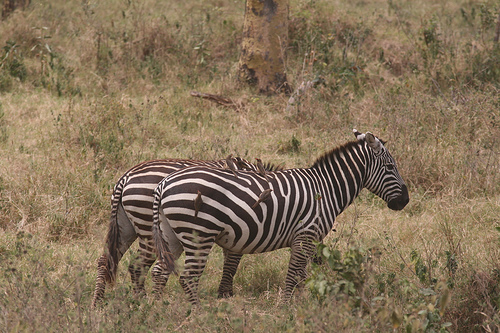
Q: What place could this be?
A: It is a field.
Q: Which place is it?
A: It is a field.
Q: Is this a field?
A: Yes, it is a field.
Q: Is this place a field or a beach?
A: It is a field.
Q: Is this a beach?
A: No, it is a field.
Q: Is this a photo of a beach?
A: No, the picture is showing a field.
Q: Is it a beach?
A: No, it is a field.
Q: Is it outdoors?
A: Yes, it is outdoors.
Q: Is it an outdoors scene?
A: Yes, it is outdoors.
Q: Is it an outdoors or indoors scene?
A: It is outdoors.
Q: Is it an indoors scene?
A: No, it is outdoors.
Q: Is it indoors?
A: No, it is outdoors.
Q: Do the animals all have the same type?
A: No, there are both zebras and birds.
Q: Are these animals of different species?
A: Yes, they are zebras and birds.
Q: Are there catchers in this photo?
A: No, there are no catchers.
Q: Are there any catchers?
A: No, there are no catchers.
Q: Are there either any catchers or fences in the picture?
A: No, there are no catchers or fences.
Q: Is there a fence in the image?
A: No, there are no fences.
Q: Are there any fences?
A: No, there are no fences.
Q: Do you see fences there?
A: No, there are no fences.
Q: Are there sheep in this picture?
A: No, there are no sheep.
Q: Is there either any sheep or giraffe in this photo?
A: No, there are no sheep or giraffes.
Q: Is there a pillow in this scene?
A: No, there are no pillows.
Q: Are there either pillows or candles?
A: No, there are no pillows or candles.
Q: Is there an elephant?
A: No, there are no elephants.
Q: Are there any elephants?
A: No, there are no elephants.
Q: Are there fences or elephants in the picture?
A: No, there are no elephants or fences.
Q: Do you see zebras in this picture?
A: Yes, there is a zebra.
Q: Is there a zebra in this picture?
A: Yes, there is a zebra.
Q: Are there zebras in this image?
A: Yes, there is a zebra.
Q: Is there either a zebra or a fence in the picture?
A: Yes, there is a zebra.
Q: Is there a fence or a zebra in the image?
A: Yes, there is a zebra.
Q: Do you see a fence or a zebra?
A: Yes, there is a zebra.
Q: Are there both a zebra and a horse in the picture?
A: No, there is a zebra but no horses.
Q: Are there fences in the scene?
A: No, there are no fences.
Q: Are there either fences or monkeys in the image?
A: No, there are no fences or monkeys.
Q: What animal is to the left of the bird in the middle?
A: The animal is a zebra.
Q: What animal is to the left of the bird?
A: The animal is a zebra.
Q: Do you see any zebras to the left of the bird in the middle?
A: Yes, there is a zebra to the left of the bird.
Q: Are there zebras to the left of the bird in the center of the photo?
A: Yes, there is a zebra to the left of the bird.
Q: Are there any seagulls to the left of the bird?
A: No, there is a zebra to the left of the bird.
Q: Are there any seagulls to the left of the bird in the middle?
A: No, there is a zebra to the left of the bird.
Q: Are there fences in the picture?
A: No, there are no fences.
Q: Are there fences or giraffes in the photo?
A: No, there are no fences or giraffes.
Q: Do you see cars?
A: No, there are no cars.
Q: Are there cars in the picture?
A: No, there are no cars.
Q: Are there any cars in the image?
A: No, there are no cars.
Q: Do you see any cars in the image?
A: No, there are no cars.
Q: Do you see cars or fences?
A: No, there are no cars or fences.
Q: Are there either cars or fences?
A: No, there are no cars or fences.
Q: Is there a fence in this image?
A: No, there are no fences.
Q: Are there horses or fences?
A: No, there are no fences or horses.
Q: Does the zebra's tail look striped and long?
A: Yes, the tail is striped and long.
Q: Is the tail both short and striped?
A: No, the tail is striped but long.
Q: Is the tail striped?
A: Yes, the tail is striped.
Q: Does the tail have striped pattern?
A: Yes, the tail is striped.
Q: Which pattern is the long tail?
A: The tail is striped.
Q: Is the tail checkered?
A: No, the tail is striped.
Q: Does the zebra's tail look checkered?
A: No, the tail is striped.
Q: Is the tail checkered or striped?
A: The tail is striped.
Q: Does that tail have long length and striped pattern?
A: Yes, the tail is long and striped.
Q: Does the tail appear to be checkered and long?
A: No, the tail is long but striped.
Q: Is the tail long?
A: Yes, the tail is long.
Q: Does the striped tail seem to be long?
A: Yes, the tail is long.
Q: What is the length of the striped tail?
A: The tail is long.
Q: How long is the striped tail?
A: The tail is long.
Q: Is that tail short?
A: No, the tail is long.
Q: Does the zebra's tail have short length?
A: No, the tail is long.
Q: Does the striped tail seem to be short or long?
A: The tail is long.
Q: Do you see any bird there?
A: Yes, there is a bird.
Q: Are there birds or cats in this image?
A: Yes, there is a bird.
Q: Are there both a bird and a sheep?
A: No, there is a bird but no sheep.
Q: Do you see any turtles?
A: No, there are no turtles.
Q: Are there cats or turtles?
A: No, there are no turtles or cats.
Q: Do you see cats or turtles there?
A: No, there are no turtles or cats.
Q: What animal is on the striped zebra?
A: The bird is on the zebra.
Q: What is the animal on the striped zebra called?
A: The animal is a bird.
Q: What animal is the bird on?
A: The bird is on the zebra.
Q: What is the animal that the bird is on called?
A: The animal is a zebra.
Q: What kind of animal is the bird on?
A: The bird is on the zebra.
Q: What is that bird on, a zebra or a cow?
A: The bird is on a zebra.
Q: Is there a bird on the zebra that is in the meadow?
A: Yes, there is a bird on the zebra.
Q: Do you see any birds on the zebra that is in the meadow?
A: Yes, there is a bird on the zebra.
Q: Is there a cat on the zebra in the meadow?
A: No, there is a bird on the zebra.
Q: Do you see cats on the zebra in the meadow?
A: No, there is a bird on the zebra.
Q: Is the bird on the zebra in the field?
A: Yes, the bird is on the zebra.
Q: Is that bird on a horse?
A: No, the bird is on the zebra.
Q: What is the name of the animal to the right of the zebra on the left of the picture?
A: The animal is a bird.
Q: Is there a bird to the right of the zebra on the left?
A: Yes, there is a bird to the right of the zebra.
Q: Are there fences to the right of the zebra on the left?
A: No, there is a bird to the right of the zebra.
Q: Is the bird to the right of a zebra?
A: Yes, the bird is to the right of a zebra.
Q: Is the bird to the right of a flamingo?
A: No, the bird is to the right of a zebra.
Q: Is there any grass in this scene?
A: Yes, there is grass.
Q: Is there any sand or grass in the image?
A: Yes, there is grass.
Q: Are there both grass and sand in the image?
A: No, there is grass but no sand.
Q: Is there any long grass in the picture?
A: Yes, there is long grass.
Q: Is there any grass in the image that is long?
A: Yes, there is grass that is long.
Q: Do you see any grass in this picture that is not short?
A: Yes, there is long grass.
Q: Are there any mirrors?
A: No, there are no mirrors.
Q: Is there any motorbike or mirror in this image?
A: No, there are no mirrors or motorcycles.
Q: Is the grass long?
A: Yes, the grass is long.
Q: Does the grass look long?
A: Yes, the grass is long.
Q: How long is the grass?
A: The grass is long.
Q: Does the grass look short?
A: No, the grass is long.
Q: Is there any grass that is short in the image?
A: No, there is grass but it is long.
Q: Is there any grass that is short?
A: No, there is grass but it is long.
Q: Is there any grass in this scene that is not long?
A: No, there is grass but it is long.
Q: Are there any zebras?
A: Yes, there is a zebra.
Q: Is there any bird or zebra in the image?
A: Yes, there is a zebra.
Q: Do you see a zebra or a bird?
A: Yes, there is a zebra.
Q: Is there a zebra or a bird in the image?
A: Yes, there is a zebra.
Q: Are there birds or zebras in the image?
A: Yes, there is a zebra.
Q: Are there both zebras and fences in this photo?
A: No, there is a zebra but no fences.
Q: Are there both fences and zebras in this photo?
A: No, there is a zebra but no fences.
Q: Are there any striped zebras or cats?
A: Yes, there is a striped zebra.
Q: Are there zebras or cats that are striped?
A: Yes, the zebra is striped.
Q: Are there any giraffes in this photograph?
A: No, there are no giraffes.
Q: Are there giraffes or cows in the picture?
A: No, there are no giraffes or cows.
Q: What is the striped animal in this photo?
A: The animal is a zebra.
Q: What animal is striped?
A: The animal is a zebra.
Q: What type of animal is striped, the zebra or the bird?
A: The zebra is striped.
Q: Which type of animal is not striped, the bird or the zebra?
A: The bird is not striped.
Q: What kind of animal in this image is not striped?
A: The animal is a bird.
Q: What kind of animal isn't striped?
A: The animal is a bird.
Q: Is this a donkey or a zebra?
A: This is a zebra.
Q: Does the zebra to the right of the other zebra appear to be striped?
A: Yes, the zebra is striped.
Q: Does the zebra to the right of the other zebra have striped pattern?
A: Yes, the zebra is striped.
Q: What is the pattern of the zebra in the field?
A: The zebra is striped.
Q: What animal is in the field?
A: The zebra is in the field.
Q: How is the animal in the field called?
A: The animal is a zebra.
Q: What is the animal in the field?
A: The animal is a zebra.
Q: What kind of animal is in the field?
A: The animal is a zebra.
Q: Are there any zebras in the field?
A: Yes, there is a zebra in the field.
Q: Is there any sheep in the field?
A: No, there is a zebra in the field.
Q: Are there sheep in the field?
A: No, there is a zebra in the field.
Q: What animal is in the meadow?
A: The zebra is in the meadow.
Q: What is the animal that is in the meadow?
A: The animal is a zebra.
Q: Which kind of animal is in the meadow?
A: The animal is a zebra.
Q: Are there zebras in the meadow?
A: Yes, there is a zebra in the meadow.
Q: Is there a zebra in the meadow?
A: Yes, there is a zebra in the meadow.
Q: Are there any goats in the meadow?
A: No, there is a zebra in the meadow.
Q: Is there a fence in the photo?
A: No, there are no fences.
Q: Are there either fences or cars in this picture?
A: No, there are no fences or cars.